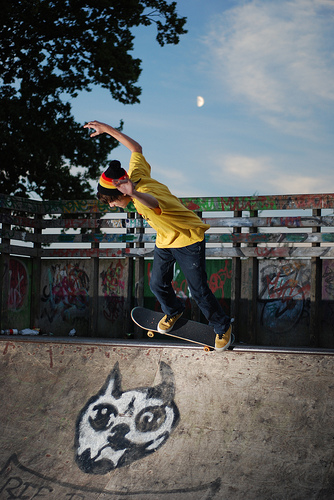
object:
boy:
[84, 119, 235, 353]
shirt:
[124, 152, 210, 249]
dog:
[75, 361, 181, 478]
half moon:
[196, 95, 204, 106]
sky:
[0, 0, 334, 244]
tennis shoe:
[157, 307, 184, 334]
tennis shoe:
[214, 321, 232, 353]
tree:
[2, 0, 181, 348]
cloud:
[123, 7, 331, 189]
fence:
[3, 194, 333, 355]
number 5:
[257, 261, 306, 336]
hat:
[98, 169, 129, 189]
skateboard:
[130, 301, 234, 353]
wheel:
[147, 331, 154, 338]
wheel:
[203, 346, 210, 352]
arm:
[102, 123, 149, 174]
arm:
[133, 186, 161, 215]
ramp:
[1, 331, 333, 500]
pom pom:
[109, 159, 121, 169]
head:
[98, 160, 132, 209]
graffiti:
[38, 262, 96, 339]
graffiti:
[99, 261, 128, 326]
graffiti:
[5, 257, 29, 311]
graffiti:
[138, 255, 233, 340]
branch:
[29, 154, 104, 222]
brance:
[2, 158, 45, 247]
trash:
[11, 327, 19, 334]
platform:
[4, 323, 330, 354]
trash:
[19, 327, 39, 335]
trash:
[68, 327, 78, 337]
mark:
[0, 340, 334, 500]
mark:
[45, 343, 53, 368]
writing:
[4, 469, 221, 500]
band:
[4, 338, 334, 363]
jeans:
[149, 241, 232, 334]